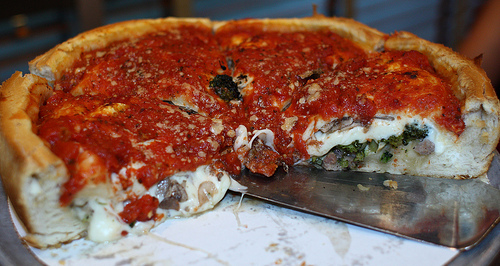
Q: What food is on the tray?
A: Pizza.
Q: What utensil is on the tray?
A: Trowel.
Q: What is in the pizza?
A: Cheese.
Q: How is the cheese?
A: Melted.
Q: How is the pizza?
A: Sliced.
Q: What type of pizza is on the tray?
A: Deep dish.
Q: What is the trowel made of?
A: Steel.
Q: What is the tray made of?
A: Cardboard.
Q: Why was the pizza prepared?
A: As a meal.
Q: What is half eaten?
A: A pizza.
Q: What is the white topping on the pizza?
A: Cheese.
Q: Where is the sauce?
A: On top of the pizza.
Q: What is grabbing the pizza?
A: A spatula.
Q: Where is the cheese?
A: Under the pizza.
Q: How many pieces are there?
A: 4.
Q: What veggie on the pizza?
A: Spinach.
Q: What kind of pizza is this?
A: Deep dish.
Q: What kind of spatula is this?
A: Metal.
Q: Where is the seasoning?
A: On the pizza.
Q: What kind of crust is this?
A: Golden brown.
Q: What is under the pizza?
A: A serving utensil.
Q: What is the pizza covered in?
A: Cheese.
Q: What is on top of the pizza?
A: Tomato sauce.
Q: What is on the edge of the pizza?
A: Crust.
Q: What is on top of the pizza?
A: Tomato sauce.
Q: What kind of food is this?
A: Pizza.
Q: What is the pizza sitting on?
A: A baking tray.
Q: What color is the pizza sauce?
A: Red.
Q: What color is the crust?
A: Light brown.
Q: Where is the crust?
A: On the outside of the pizza.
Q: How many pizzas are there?
A: One.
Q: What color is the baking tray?
A: Silver.